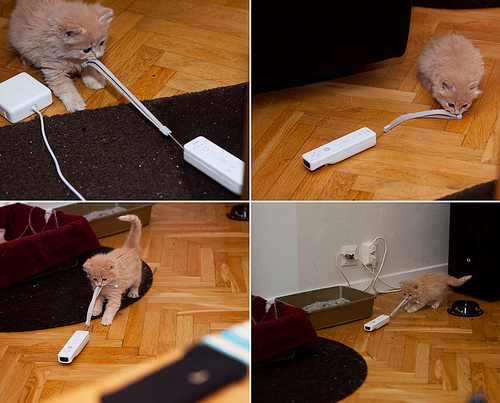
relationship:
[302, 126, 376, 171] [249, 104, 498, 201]
game controller on floor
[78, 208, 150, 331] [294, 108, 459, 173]
kitten with game controller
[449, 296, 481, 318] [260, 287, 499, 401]
bowl on floor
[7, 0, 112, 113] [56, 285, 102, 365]
kitty pulling controller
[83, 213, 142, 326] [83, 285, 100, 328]
kitten pulling strap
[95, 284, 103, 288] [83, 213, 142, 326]
mouth on kitten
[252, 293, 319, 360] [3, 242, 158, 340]
box on carpet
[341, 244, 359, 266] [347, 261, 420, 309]
outlet with wires